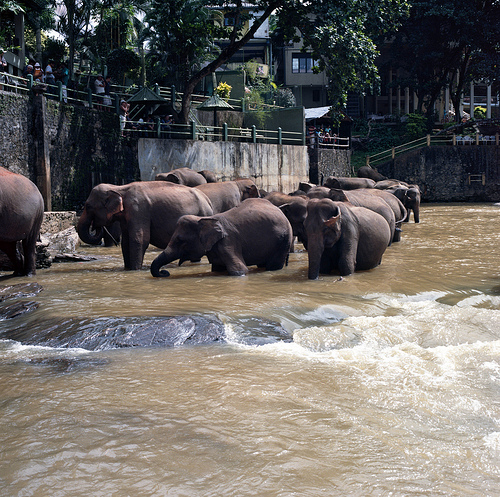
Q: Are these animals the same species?
A: Yes, all the animals are elephants.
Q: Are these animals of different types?
A: No, all the animals are elephants.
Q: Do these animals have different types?
A: No, all the animals are elephants.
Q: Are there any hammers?
A: No, there are no hammers.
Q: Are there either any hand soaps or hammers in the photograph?
A: No, there are no hammers or hand soaps.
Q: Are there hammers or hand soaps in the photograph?
A: No, there are no hammers or hand soaps.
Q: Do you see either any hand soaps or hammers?
A: No, there are no hammers or hand soaps.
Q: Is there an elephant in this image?
A: Yes, there is an elephant.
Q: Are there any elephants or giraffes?
A: Yes, there is an elephant.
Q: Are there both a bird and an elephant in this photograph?
A: No, there is an elephant but no birds.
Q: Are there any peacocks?
A: No, there are no peacocks.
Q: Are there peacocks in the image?
A: No, there are no peacocks.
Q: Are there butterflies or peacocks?
A: No, there are no peacocks or butterflies.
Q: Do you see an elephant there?
A: Yes, there is an elephant.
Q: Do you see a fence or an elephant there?
A: Yes, there is an elephant.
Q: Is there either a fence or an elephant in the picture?
A: Yes, there is an elephant.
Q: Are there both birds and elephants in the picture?
A: No, there is an elephant but no birds.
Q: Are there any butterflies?
A: No, there are no butterflies.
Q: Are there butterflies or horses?
A: No, there are no butterflies or horses.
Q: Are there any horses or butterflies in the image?
A: No, there are no butterflies or horses.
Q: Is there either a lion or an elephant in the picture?
A: Yes, there is an elephant.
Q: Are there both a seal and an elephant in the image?
A: No, there is an elephant but no seals.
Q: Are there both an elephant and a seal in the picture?
A: No, there is an elephant but no seals.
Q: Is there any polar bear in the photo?
A: No, there are no polar bears.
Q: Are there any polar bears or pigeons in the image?
A: No, there are no polar bears or pigeons.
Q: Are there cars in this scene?
A: No, there are no cars.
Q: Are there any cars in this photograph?
A: No, there are no cars.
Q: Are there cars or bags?
A: No, there are no cars or bags.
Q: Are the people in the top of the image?
A: Yes, the people are in the top of the image.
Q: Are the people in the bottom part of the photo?
A: No, the people are in the top of the image.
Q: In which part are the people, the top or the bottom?
A: The people are in the top of the image.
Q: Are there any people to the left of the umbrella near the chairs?
A: Yes, there are people to the left of the umbrella.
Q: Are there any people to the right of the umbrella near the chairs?
A: No, the people are to the left of the umbrella.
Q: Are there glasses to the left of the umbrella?
A: No, there are people to the left of the umbrella.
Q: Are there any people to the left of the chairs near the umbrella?
A: Yes, there are people to the left of the chairs.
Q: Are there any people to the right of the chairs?
A: No, the people are to the left of the chairs.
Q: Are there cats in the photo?
A: No, there are no cats.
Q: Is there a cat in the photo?
A: No, there are no cats.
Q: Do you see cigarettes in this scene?
A: No, there are no cigarettes.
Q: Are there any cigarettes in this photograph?
A: No, there are no cigarettes.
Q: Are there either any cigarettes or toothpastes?
A: No, there are no cigarettes or toothpastes.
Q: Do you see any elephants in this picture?
A: Yes, there is an elephant.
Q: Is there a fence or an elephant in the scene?
A: Yes, there is an elephant.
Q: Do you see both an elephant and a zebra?
A: No, there is an elephant but no zebras.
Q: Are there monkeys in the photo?
A: No, there are no monkeys.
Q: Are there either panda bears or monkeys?
A: No, there are no monkeys or panda bears.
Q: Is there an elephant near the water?
A: Yes, there is an elephant near the water.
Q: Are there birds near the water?
A: No, there is an elephant near the water.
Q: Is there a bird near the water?
A: No, there is an elephant near the water.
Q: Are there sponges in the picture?
A: No, there are no sponges.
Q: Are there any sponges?
A: No, there are no sponges.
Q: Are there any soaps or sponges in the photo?
A: No, there are no sponges or soaps.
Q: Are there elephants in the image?
A: Yes, there is an elephant.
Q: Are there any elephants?
A: Yes, there is an elephant.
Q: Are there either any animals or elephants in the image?
A: Yes, there is an elephant.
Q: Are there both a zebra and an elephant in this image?
A: No, there is an elephant but no zebras.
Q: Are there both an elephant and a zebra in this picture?
A: No, there is an elephant but no zebras.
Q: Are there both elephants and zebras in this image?
A: No, there is an elephant but no zebras.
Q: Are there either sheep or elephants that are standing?
A: Yes, the elephant is standing.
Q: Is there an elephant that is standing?
A: Yes, there is an elephant that is standing.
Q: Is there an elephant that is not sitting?
A: Yes, there is an elephant that is standing.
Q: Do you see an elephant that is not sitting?
A: Yes, there is an elephant that is standing .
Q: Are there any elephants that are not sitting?
A: Yes, there is an elephant that is standing.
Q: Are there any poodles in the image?
A: No, there are no poodles.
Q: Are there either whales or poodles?
A: No, there are no poodles or whales.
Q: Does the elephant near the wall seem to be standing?
A: Yes, the elephant is standing.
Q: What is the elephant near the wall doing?
A: The elephant is standing.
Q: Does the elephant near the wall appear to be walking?
A: No, the elephant is standing.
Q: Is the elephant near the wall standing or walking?
A: The elephant is standing.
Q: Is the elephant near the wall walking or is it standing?
A: The elephant is standing.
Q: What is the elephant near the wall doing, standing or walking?
A: The elephant is standing.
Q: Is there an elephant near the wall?
A: Yes, there is an elephant near the wall.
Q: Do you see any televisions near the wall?
A: No, there is an elephant near the wall.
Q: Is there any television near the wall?
A: No, there is an elephant near the wall.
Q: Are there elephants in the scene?
A: Yes, there is an elephant.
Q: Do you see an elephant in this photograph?
A: Yes, there is an elephant.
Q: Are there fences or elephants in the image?
A: Yes, there is an elephant.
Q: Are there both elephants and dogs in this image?
A: No, there is an elephant but no dogs.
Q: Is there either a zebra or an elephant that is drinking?
A: Yes, the elephant is drinking.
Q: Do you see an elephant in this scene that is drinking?
A: Yes, there is an elephant that is drinking.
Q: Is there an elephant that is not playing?
A: Yes, there is an elephant that is drinking.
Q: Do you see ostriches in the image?
A: No, there are no ostriches.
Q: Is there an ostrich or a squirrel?
A: No, there are no ostriches or squirrels.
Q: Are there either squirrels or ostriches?
A: No, there are no ostriches or squirrels.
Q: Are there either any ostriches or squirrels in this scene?
A: No, there are no ostriches or squirrels.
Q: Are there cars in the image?
A: No, there are no cars.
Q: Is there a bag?
A: No, there are no bags.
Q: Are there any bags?
A: No, there are no bags.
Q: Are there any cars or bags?
A: No, there are no bags or cars.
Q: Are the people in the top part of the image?
A: Yes, the people are in the top of the image.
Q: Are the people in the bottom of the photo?
A: No, the people are in the top of the image.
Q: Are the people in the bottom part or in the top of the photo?
A: The people are in the top of the image.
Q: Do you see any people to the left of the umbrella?
A: Yes, there are people to the left of the umbrella.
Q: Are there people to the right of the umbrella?
A: No, the people are to the left of the umbrella.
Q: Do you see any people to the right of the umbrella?
A: No, the people are to the left of the umbrella.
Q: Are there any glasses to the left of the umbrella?
A: No, there are people to the left of the umbrella.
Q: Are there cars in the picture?
A: No, there are no cars.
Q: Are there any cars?
A: No, there are no cars.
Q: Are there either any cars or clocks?
A: No, there are no cars or clocks.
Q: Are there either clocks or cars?
A: No, there are no cars or clocks.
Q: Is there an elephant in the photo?
A: Yes, there is an elephant.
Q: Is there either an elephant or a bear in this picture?
A: Yes, there is an elephant.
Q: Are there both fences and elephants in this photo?
A: Yes, there are both an elephant and a fence.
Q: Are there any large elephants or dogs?
A: Yes, there is a large elephant.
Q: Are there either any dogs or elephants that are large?
A: Yes, the elephant is large.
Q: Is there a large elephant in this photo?
A: Yes, there is a large elephant.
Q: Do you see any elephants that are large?
A: Yes, there is an elephant that is large.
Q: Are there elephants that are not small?
A: Yes, there is a large elephant.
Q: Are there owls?
A: No, there are no owls.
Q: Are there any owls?
A: No, there are no owls.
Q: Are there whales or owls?
A: No, there are no owls or whales.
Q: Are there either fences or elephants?
A: Yes, there is an elephant.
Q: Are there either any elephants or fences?
A: Yes, there is an elephant.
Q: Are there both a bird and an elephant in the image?
A: No, there is an elephant but no birds.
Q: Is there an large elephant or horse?
A: Yes, there is a large elephant.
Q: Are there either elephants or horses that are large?
A: Yes, the elephant is large.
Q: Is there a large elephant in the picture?
A: Yes, there is a large elephant.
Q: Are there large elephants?
A: Yes, there is a large elephant.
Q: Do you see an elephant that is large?
A: Yes, there is a large elephant.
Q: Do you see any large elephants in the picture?
A: Yes, there is a large elephant.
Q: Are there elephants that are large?
A: Yes, there is an elephant that is large.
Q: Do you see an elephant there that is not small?
A: Yes, there is a large elephant.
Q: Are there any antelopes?
A: No, there are no antelopes.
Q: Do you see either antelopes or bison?
A: No, there are no antelopes or bison.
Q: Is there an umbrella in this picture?
A: Yes, there is an umbrella.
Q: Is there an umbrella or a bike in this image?
A: Yes, there is an umbrella.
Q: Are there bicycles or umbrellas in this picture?
A: Yes, there is an umbrella.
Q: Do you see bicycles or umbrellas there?
A: Yes, there is an umbrella.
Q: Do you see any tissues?
A: No, there are no tissues.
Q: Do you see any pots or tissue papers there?
A: No, there are no tissue papers or pots.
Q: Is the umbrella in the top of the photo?
A: Yes, the umbrella is in the top of the image.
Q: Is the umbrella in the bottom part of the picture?
A: No, the umbrella is in the top of the image.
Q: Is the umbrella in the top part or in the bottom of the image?
A: The umbrella is in the top of the image.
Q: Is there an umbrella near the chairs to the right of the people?
A: Yes, there is an umbrella near the chairs.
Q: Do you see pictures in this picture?
A: No, there are no pictures.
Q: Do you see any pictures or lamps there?
A: No, there are no pictures or lamps.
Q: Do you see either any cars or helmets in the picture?
A: No, there are no cars or helmets.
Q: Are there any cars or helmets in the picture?
A: No, there are no cars or helmets.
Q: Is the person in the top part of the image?
A: Yes, the person is in the top of the image.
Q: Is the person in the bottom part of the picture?
A: No, the person is in the top of the image.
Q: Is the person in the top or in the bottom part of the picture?
A: The person is in the top of the image.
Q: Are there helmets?
A: No, there are no helmets.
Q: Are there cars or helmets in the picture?
A: No, there are no helmets or cars.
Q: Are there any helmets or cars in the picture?
A: No, there are no helmets or cars.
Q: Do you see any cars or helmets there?
A: No, there are no helmets or cars.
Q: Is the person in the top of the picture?
A: Yes, the person is in the top of the image.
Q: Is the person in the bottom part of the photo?
A: No, the person is in the top of the image.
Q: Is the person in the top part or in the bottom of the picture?
A: The person is in the top of the image.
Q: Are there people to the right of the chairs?
A: Yes, there is a person to the right of the chairs.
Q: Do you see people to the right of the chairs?
A: Yes, there is a person to the right of the chairs.